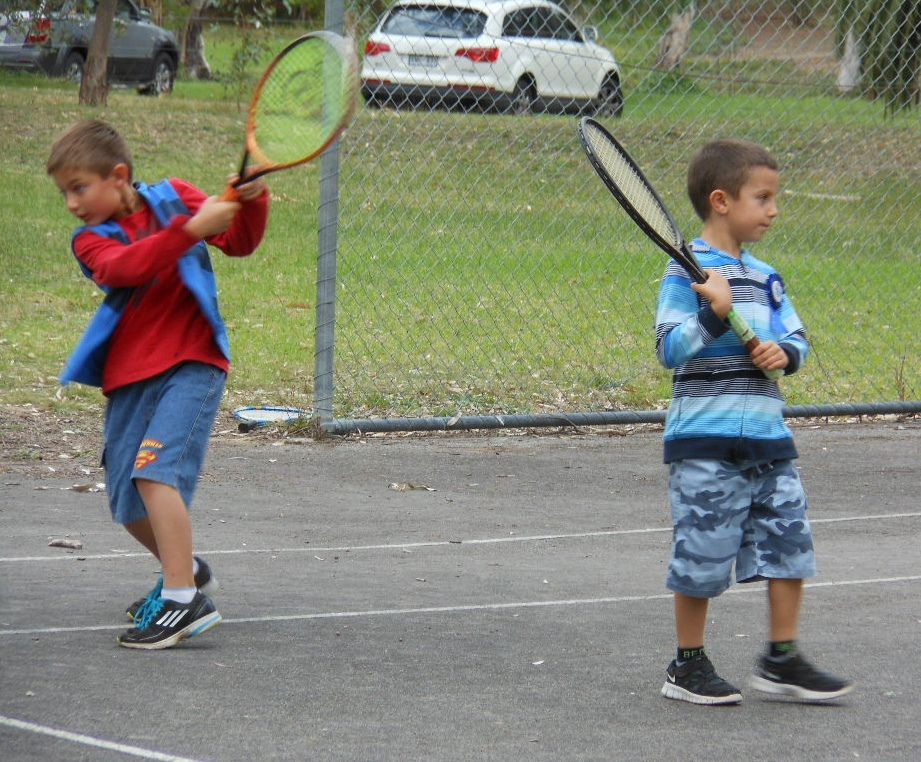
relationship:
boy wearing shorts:
[655, 138, 856, 705] [672, 452, 816, 606]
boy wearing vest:
[45, 120, 267, 650] [66, 180, 228, 375]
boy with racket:
[655, 138, 856, 705] [569, 105, 714, 285]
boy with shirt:
[655, 138, 856, 705] [667, 246, 797, 455]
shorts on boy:
[672, 452, 816, 606] [655, 138, 856, 705]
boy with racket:
[45, 120, 267, 650] [223, 23, 380, 212]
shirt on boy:
[59, 216, 228, 373] [45, 120, 267, 650]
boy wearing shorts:
[26, 118, 250, 662] [95, 361, 220, 535]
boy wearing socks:
[26, 118, 250, 662] [150, 572, 205, 605]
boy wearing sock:
[45, 120, 267, 650] [156, 579, 202, 608]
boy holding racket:
[649, 139, 848, 712] [577, 116, 709, 285]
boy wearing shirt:
[649, 139, 848, 712] [649, 240, 809, 475]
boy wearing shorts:
[649, 139, 848, 712] [662, 449, 824, 596]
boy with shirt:
[45, 120, 267, 650] [71, 175, 263, 382]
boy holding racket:
[45, 120, 267, 650] [222, 25, 357, 200]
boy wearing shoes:
[45, 120, 267, 650] [102, 554, 214, 644]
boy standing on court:
[655, 138, 856, 705] [38, 417, 915, 758]